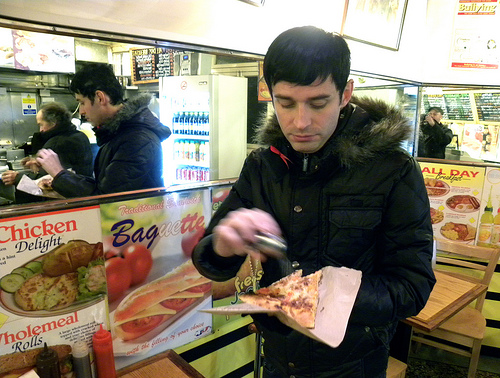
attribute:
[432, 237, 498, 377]
chair — wooden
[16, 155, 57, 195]
pizza — pieces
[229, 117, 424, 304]
coat — black 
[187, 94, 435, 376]
coat — black 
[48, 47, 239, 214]
mirror — long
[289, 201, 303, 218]
button — black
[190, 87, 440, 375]
jacket — parka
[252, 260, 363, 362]
pizza — large, slice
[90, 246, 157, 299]
photo — two tomatoes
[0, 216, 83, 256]
words — Chicken Delight